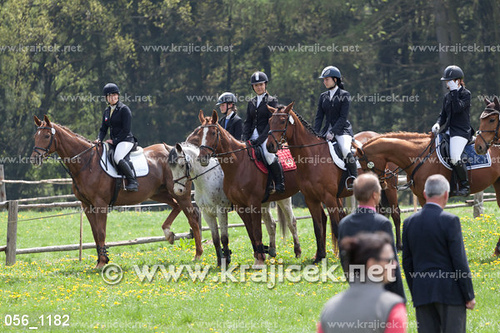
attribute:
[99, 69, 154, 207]
person — sitting down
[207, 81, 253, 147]
person — sitting down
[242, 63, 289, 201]
person — sitting down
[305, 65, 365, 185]
person — sitting down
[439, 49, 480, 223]
person — sitting down